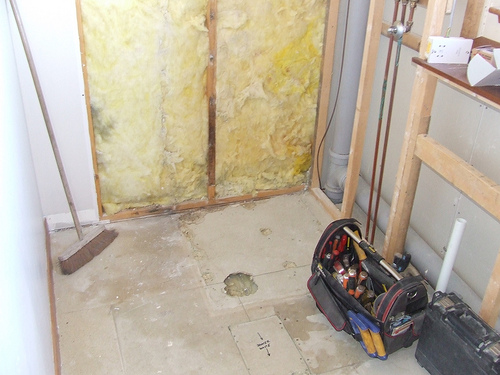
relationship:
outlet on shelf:
[428, 32, 478, 66] [408, 34, 499, 105]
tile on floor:
[231, 313, 305, 374] [48, 191, 422, 374]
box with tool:
[308, 216, 429, 345] [360, 265, 398, 292]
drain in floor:
[223, 271, 259, 300] [48, 191, 422, 374]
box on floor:
[308, 216, 429, 345] [48, 191, 422, 374]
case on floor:
[414, 289, 499, 373] [48, 191, 422, 374]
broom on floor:
[11, 0, 117, 272] [48, 191, 422, 374]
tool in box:
[360, 265, 398, 292] [308, 216, 429, 345]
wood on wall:
[417, 133, 498, 215] [305, 3, 499, 338]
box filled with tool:
[308, 216, 429, 345] [360, 265, 398, 292]